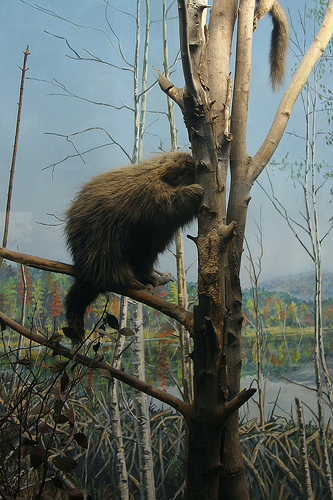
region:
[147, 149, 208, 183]
Face against the tree.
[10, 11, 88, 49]
The sky is blue.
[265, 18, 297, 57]
The tail is tan.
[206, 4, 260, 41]
The tree is tan.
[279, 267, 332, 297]
Mountain in the distance.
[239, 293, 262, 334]
Green tree in the painting.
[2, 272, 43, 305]
The tree is red.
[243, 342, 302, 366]
Reflection in the water.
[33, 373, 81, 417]
Leaves on the twig.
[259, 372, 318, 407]
The water is blue.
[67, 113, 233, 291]
Furry beaver on tree branch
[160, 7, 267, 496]
Tall brown tree trunks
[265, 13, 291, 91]
Bushy tail of second animal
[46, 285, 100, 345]
Bushy tail of beaver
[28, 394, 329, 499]
Beaver's nest under beaver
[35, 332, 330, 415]
Painted lake in background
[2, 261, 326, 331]
red and green trees around lake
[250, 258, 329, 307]
Tree covered mountains in background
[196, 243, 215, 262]
Bite marks along tree trunk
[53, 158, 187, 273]
Long brown fur on beaver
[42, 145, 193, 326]
taxidermied animal in tree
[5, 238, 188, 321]
branch taxidermied animal is perched on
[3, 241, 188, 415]
two branches of tree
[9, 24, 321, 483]
lake scene painted on wall behind tree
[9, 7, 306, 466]
tree trunk and branches with no leaves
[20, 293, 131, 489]
branch with dried leaves on it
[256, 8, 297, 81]
tail of animal in top of tree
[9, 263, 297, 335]
trees with red or green leaves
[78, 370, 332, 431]
white reflection on lake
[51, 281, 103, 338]
tail of taxidermied animal on branch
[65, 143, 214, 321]
brown beaver in tree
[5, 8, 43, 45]
white clouds in blue sky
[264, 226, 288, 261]
white clouds in blue sky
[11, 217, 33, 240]
white clouds in blue sky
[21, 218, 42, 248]
white clouds in blue sky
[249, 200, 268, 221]
white clouds in blue sky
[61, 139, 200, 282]
brown beaver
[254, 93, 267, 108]
white clouds in blue sky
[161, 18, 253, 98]
brown branches with no leaves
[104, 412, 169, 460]
brown branches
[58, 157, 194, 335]
beaver standing in tree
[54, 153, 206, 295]
long fur of animal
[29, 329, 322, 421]
lake behind the tree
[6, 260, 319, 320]
green and red trees along river bank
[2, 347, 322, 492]
sticks behind tree trunk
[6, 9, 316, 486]
painting of lake scene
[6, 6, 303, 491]
tree with taxidermied animals in it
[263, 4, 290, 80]
tail of animal at top of tree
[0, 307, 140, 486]
dried plant beside tree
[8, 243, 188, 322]
branch animals is standing on